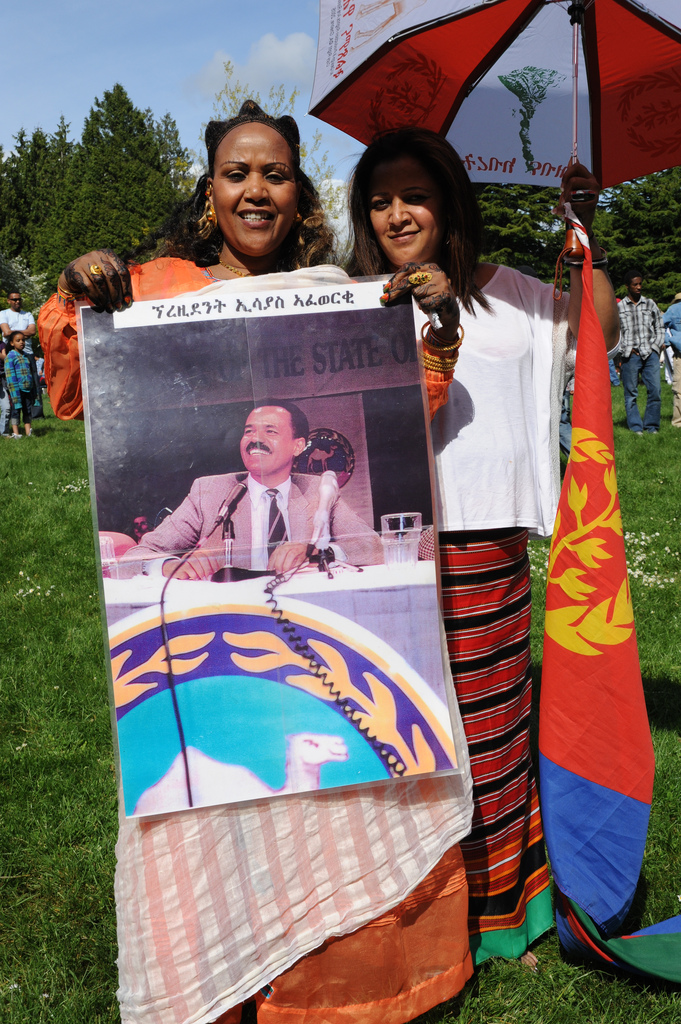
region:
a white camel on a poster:
[131, 730, 346, 819]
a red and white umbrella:
[313, 3, 679, 203]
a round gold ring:
[88, 263, 107, 280]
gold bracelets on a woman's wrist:
[414, 308, 464, 379]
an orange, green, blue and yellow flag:
[527, 196, 678, 980]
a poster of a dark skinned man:
[61, 276, 464, 818]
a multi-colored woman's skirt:
[415, 507, 558, 968]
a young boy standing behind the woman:
[3, 331, 51, 443]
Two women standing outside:
[50, 91, 610, 1022]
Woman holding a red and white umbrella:
[307, 0, 676, 985]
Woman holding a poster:
[53, 100, 475, 1022]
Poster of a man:
[75, 281, 462, 812]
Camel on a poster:
[136, 725, 349, 812]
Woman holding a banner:
[316, 129, 676, 998]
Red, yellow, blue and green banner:
[524, 225, 675, 988]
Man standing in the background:
[607, 271, 673, 431]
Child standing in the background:
[3, 326, 42, 432]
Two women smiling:
[51, 96, 617, 1010]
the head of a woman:
[202, 114, 314, 277]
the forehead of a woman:
[225, 116, 277, 166]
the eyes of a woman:
[227, 162, 289, 189]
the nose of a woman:
[249, 172, 268, 207]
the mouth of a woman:
[233, 205, 277, 228]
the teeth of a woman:
[249, 209, 260, 228]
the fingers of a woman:
[56, 269, 137, 317]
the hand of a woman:
[70, 250, 147, 314]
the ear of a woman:
[188, 160, 223, 206]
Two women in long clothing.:
[30, 93, 569, 1022]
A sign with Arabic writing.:
[73, 271, 464, 823]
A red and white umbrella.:
[306, 3, 676, 209]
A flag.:
[529, 195, 679, 979]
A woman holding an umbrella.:
[295, 2, 677, 971]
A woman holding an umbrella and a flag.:
[305, 6, 679, 1001]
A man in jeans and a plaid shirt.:
[611, 268, 670, 434]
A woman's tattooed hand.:
[57, 246, 135, 317]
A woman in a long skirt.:
[34, 95, 493, 1022]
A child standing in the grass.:
[3, 327, 39, 441]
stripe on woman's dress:
[435, 515, 528, 554]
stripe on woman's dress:
[435, 558, 530, 590]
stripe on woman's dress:
[437, 589, 535, 633]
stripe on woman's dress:
[444, 630, 534, 676]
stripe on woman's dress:
[456, 711, 532, 753]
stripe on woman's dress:
[471, 760, 530, 793]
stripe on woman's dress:
[458, 791, 539, 843]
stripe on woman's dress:
[462, 845, 527, 884]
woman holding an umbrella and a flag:
[335, 119, 626, 977]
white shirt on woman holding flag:
[351, 244, 566, 532]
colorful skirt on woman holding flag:
[430, 525, 559, 966]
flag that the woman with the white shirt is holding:
[534, 220, 677, 984]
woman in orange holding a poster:
[31, 97, 480, 1021]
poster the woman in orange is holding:
[57, 278, 481, 823]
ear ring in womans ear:
[189, 192, 220, 239]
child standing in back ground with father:
[3, 327, 39, 438]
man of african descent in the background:
[600, 270, 672, 436]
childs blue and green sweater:
[3, 346, 41, 410]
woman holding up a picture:
[50, 104, 422, 812]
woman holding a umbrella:
[350, 109, 595, 900]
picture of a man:
[101, 337, 409, 671]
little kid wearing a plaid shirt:
[5, 328, 44, 433]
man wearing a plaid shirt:
[618, 265, 675, 427]